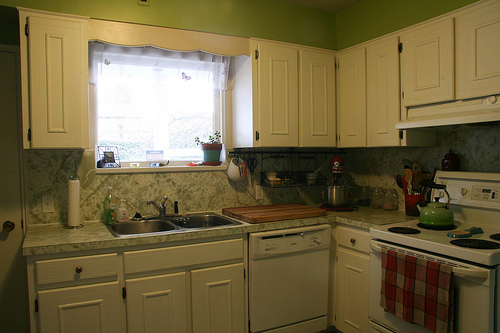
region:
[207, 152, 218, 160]
blue paint on flower pot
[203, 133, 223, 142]
flowers in flower pot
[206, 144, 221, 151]
burgandy paint on pot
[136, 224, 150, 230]
inside of sink on left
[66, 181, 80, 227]
tall roll of paper towel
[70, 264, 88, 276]
gold knob on drawer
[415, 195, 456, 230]
green tea kettle on stove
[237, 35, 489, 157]
the cabinets are white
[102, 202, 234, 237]
the sink is silver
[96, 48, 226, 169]
the curtain is sheer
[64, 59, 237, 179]
the light is coming through the window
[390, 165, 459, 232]
a tea pot on the stove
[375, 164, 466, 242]
the teapot is green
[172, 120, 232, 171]
a potted plant on the window sill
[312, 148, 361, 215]
a mixer on the counter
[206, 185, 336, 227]
a cutting board on the counter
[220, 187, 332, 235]
the cutting board is made of wood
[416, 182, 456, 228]
Green kettle on stove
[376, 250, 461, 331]
Checked mat on stove handle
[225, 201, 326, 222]
Brown wooden cutting board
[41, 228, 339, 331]
Cream colored kitchen cabinets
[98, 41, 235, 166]
A window in the kitchen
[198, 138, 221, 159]
Vase on the window sill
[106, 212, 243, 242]
Two stainless kitchen sinks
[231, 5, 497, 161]
Wooden cabinets in kitchen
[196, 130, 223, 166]
Green flowers in a vase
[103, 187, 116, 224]
Bottle of soap on counter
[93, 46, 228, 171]
window is above kitchen sink.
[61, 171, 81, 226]
paper towel holder on counter.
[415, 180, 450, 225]
green teakettle on back burner.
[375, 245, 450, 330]
red and white checkered towel hanging from over door handle.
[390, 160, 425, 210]
red utensil holder full of cooking utensils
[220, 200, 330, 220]
wooden cutting board on counter top.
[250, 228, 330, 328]
white dishwasher under counter top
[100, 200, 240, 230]
double kitchen sink is silver.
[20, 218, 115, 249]
kitchen counter top is green and white.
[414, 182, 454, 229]
Green kettle on the stove.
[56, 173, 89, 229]
Paper towels on metal holder.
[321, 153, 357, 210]
Red and metal mixer on counter.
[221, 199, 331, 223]
Wooden cutting board on counter.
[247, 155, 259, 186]
Scissors hanging on wall.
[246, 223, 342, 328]
Dishwasher under kitchen counter.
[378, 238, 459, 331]
Red and white checkered towel.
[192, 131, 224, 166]
Potted plant on window sill.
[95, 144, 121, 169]
Framed picture on window sill.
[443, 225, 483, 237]
Spoon holder on stove.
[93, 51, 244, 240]
square window above silver sink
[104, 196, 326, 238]
wooden cutting board next to silver sink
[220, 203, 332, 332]
wooden cutting board above white dishwasher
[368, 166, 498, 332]
green tea kettle on white stove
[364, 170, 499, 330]
plaid towel hanging on white stove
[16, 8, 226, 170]
white cabinet next to window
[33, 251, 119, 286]
metal knob on white draw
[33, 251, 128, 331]
white draw above white painted cabinet